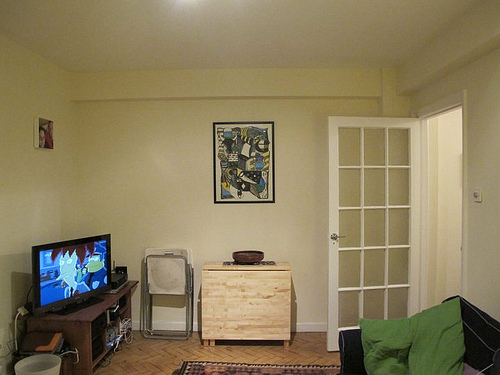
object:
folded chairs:
[137, 249, 196, 342]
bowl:
[231, 250, 265, 264]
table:
[198, 261, 296, 347]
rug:
[173, 359, 343, 374]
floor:
[87, 328, 339, 373]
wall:
[65, 60, 418, 336]